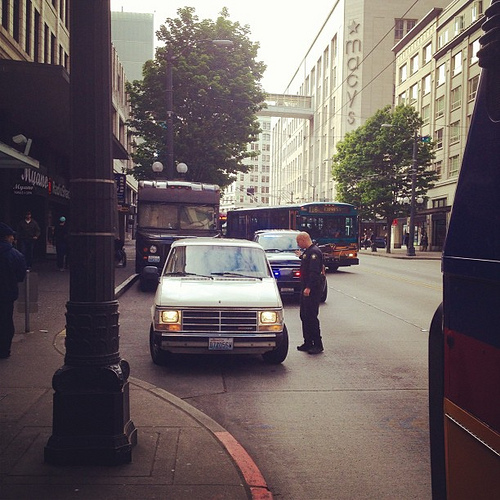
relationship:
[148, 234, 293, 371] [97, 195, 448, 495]
car on street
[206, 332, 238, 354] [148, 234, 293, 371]
license plate on car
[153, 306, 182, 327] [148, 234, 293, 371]
headlight on car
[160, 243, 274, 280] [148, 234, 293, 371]
windshield on car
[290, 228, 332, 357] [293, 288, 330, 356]
man wearing pants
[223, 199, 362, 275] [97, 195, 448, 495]
bus on street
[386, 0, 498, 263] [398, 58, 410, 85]
building has window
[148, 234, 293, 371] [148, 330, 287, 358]
car has bumper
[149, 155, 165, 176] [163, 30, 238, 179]
streetlight on pole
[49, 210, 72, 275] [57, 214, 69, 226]
man wearing cap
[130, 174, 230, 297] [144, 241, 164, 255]
truck has headlight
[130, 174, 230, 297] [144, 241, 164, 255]
van has headlight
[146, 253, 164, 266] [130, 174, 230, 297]
tag on van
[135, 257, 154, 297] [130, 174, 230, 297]
tire on van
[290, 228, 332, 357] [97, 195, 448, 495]
police officer in street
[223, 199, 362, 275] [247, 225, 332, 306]
bus behind car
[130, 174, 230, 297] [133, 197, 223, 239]
van has windshield